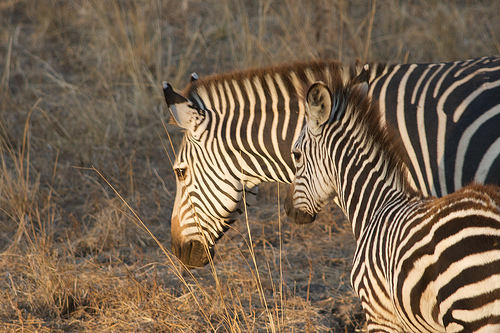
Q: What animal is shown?
A: Zebras.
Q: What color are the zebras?
A: Black and white.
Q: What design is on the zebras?
A: Stripes.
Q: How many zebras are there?
A: 2.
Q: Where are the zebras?
A: In the wild.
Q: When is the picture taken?
A: Daytime.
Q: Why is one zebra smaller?
A: It's a baby zebra.